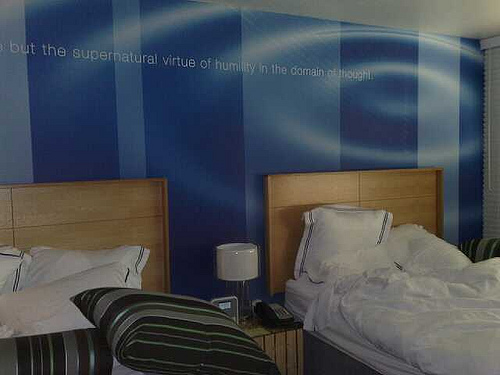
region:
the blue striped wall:
[2, 1, 499, 293]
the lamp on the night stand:
[213, 240, 265, 327]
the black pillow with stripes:
[75, 288, 278, 374]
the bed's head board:
[265, 164, 450, 285]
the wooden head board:
[0, 180, 175, 315]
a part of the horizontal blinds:
[478, 38, 498, 233]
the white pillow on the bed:
[291, 203, 386, 278]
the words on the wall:
[5, 37, 376, 86]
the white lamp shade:
[214, 240, 261, 282]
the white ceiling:
[252, 1, 499, 39]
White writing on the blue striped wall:
[0, 37, 374, 82]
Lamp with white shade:
[207, 234, 264, 322]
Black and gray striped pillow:
[66, 276, 278, 373]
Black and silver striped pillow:
[0, 321, 112, 373]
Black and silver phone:
[250, 298, 297, 330]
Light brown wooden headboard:
[261, 165, 446, 293]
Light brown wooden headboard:
[0, 176, 172, 296]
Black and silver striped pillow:
[453, 235, 498, 262]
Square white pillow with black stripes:
[292, 205, 396, 284]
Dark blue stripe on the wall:
[140, 0, 245, 302]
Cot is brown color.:
[7, 145, 460, 337]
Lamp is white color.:
[206, 235, 286, 300]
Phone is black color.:
[246, 286, 287, 341]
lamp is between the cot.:
[210, 225, 270, 311]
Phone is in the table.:
[250, 285, 300, 350]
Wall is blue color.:
[95, 55, 350, 140]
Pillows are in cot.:
[25, 220, 425, 335]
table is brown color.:
[241, 320, 306, 370]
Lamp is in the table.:
[214, 255, 275, 331]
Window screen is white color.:
[461, 67, 498, 242]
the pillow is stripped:
[102, 288, 247, 374]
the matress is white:
[298, 201, 415, 266]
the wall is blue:
[129, 68, 359, 150]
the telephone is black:
[257, 287, 312, 344]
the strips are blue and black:
[120, 287, 232, 361]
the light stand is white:
[203, 230, 286, 294]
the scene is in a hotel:
[4, 14, 497, 364]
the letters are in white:
[21, 38, 388, 113]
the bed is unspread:
[283, 175, 498, 374]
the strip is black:
[368, 213, 401, 252]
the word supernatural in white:
[71, 46, 159, 66]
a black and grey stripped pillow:
[75, 273, 277, 373]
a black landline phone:
[257, 293, 292, 325]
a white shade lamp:
[213, 241, 262, 325]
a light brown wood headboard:
[263, 167, 445, 287]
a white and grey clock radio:
[206, 291, 243, 331]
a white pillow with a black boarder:
[296, 201, 391, 281]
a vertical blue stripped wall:
[1, 0, 489, 266]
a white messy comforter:
[308, 238, 499, 373]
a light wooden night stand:
[229, 311, 306, 372]